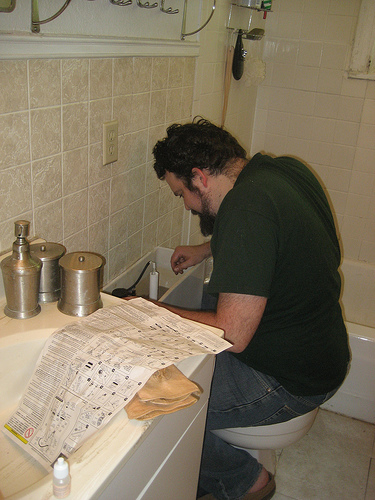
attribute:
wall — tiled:
[56, 68, 134, 187]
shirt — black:
[213, 169, 352, 384]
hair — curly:
[132, 111, 245, 185]